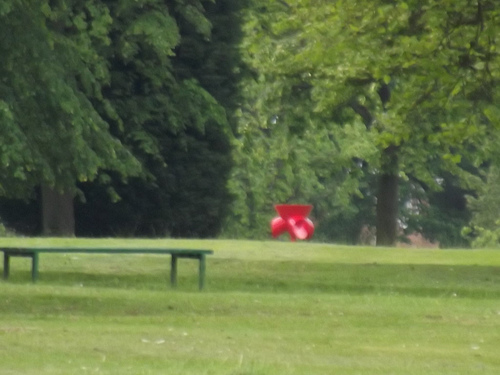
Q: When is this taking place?
A: Daytime.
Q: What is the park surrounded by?
A: Trees and foliage.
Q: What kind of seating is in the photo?
A: Bench.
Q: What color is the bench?
A: Green.